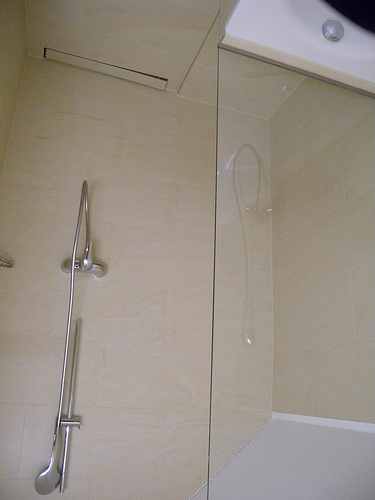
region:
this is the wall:
[115, 351, 130, 382]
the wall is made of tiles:
[93, 395, 162, 483]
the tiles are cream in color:
[85, 388, 163, 469]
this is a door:
[226, 135, 266, 193]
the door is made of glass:
[245, 359, 291, 420]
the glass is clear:
[242, 415, 269, 445]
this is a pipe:
[37, 173, 88, 497]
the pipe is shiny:
[54, 449, 62, 463]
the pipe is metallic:
[47, 461, 64, 479]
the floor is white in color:
[284, 419, 343, 476]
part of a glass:
[226, 381, 278, 431]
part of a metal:
[55, 403, 90, 455]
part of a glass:
[210, 369, 236, 417]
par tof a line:
[230, 416, 254, 452]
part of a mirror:
[196, 422, 227, 470]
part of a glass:
[61, 366, 141, 474]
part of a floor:
[270, 417, 285, 444]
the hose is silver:
[59, 200, 90, 358]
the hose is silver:
[30, 192, 111, 388]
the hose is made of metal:
[32, 232, 108, 379]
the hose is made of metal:
[46, 241, 81, 340]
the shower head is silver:
[32, 326, 93, 497]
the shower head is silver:
[11, 393, 77, 496]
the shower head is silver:
[25, 410, 121, 497]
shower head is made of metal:
[25, 407, 99, 497]